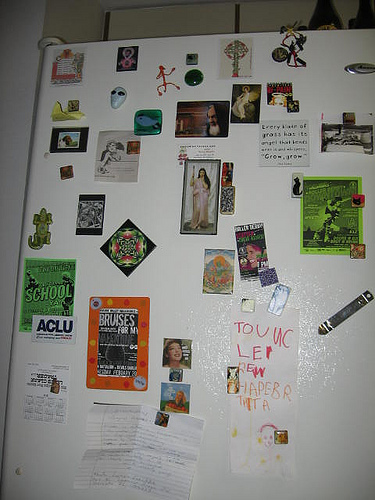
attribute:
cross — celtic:
[216, 34, 255, 79]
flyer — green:
[294, 174, 364, 259]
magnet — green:
[130, 105, 165, 140]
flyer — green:
[295, 170, 370, 262]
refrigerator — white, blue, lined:
[2, 23, 374, 493]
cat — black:
[288, 172, 305, 197]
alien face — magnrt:
[107, 80, 130, 114]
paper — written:
[70, 403, 207, 497]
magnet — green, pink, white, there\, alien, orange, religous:
[110, 84, 126, 113]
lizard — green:
[23, 208, 55, 253]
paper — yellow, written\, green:
[47, 97, 85, 126]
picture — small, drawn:
[163, 336, 195, 365]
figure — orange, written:
[280, 24, 309, 54]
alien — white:
[113, 86, 125, 105]